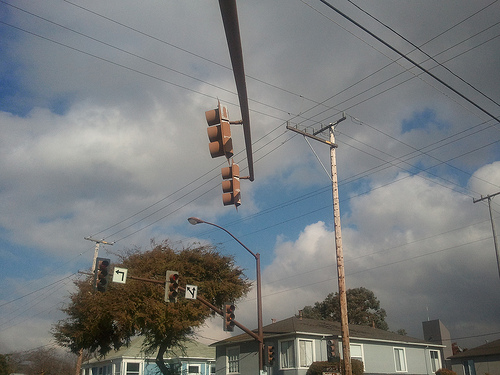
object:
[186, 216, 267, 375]
street light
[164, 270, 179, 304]
traffic signal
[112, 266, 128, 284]
sign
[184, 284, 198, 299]
sign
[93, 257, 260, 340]
arm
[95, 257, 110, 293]
traffic signal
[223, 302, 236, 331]
traffic signal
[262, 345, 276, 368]
traffic signal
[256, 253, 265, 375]
pole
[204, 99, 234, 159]
traffic signal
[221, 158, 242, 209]
traffic signal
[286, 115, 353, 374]
utility pole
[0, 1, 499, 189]
sky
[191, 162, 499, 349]
clouds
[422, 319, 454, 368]
building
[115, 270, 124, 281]
arrow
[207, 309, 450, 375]
house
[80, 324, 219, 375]
house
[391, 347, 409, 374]
window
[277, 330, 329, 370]
corner window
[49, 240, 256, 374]
tree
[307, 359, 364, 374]
bush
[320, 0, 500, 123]
power line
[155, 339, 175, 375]
trunk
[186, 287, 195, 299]
arrows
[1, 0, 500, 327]
wires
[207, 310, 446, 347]
roof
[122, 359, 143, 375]
window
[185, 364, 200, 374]
window